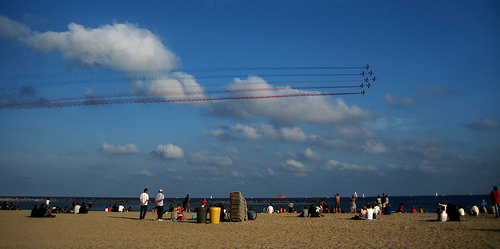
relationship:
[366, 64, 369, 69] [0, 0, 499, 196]
jet in sky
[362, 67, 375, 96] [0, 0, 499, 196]
jet in sky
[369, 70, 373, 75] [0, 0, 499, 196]
jet in sky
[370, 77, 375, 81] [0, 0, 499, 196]
jet in sky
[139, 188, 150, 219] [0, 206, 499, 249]
person on beach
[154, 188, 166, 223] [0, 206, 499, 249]
person on beach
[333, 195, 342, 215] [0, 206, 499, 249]
person on beach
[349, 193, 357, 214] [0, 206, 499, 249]
person on beach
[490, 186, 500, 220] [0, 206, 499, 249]
person on beach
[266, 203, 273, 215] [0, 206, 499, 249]
person on beach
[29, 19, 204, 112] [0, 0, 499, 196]
cloud in sky